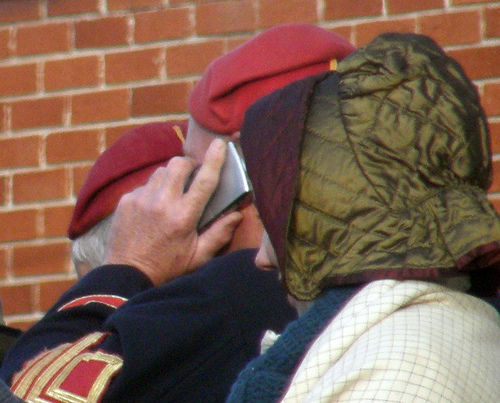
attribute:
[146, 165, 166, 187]
finger — white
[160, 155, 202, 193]
finger — white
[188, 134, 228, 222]
finger — white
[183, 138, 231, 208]
finger — white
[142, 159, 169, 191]
finger — white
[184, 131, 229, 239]
finger — whtie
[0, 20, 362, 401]
person — talking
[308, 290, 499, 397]
shoulder — white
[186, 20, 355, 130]
cap — red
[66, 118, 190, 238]
cap — red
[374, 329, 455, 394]
jacket — white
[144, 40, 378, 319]
man — wearing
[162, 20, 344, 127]
hat — red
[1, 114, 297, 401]
man — wearing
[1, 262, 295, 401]
jacket — blue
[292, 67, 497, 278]
hood — green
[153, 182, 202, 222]
hand —  white 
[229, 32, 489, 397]
woman — wearing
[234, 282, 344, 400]
scarf — green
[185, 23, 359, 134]
hat — red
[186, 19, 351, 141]
hat — red